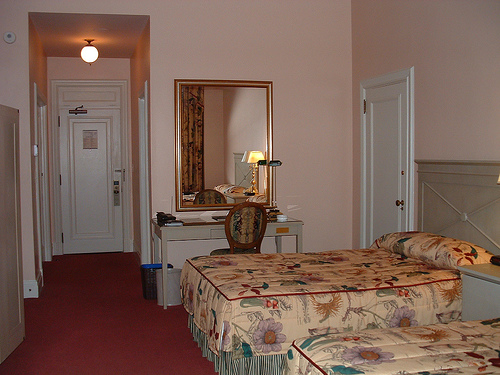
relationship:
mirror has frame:
[169, 73, 282, 216] [172, 78, 276, 213]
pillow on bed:
[366, 221, 499, 274] [164, 226, 500, 375]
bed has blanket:
[164, 226, 500, 375] [178, 249, 456, 338]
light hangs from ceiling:
[76, 40, 102, 68] [30, 13, 143, 62]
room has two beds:
[3, 4, 500, 373] [164, 226, 500, 375]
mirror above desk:
[169, 73, 282, 216] [144, 208, 312, 318]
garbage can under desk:
[138, 257, 171, 308] [144, 208, 312, 318]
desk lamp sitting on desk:
[258, 156, 288, 222] [144, 208, 312, 318]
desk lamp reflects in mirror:
[258, 156, 288, 222] [169, 73, 282, 216]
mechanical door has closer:
[47, 75, 138, 258] [64, 101, 91, 120]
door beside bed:
[353, 74, 416, 247] [178, 226, 496, 353]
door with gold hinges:
[47, 75, 138, 258] [53, 110, 70, 253]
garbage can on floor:
[138, 257, 171, 308] [16, 296, 199, 371]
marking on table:
[271, 225, 294, 235] [144, 208, 312, 318]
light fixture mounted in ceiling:
[76, 34, 100, 48] [30, 13, 143, 62]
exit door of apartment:
[47, 75, 138, 258] [3, 4, 500, 373]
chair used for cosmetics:
[215, 195, 275, 256] [185, 208, 228, 223]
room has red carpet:
[3, 4, 500, 373] [16, 241, 196, 374]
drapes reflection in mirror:
[179, 83, 209, 190] [169, 73, 282, 216]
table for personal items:
[144, 208, 312, 318] [151, 211, 291, 225]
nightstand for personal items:
[453, 256, 499, 325] [472, 253, 500, 278]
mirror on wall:
[169, 73, 282, 216] [147, 4, 356, 253]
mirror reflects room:
[169, 73, 282, 216] [3, 4, 500, 373]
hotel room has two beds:
[3, 4, 500, 373] [164, 226, 500, 375]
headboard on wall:
[410, 153, 500, 256] [412, 3, 500, 160]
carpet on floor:
[6, 237, 208, 373] [16, 241, 196, 374]